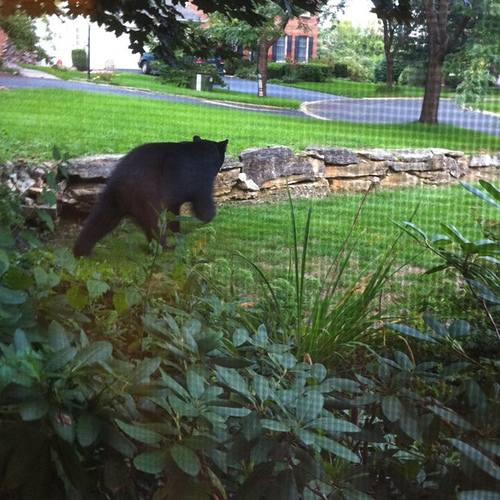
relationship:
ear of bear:
[190, 125, 206, 140] [90, 112, 255, 279]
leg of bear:
[191, 190, 214, 223] [73, 134, 229, 256]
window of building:
[292, 32, 309, 66] [166, 5, 321, 71]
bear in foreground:
[73, 134, 229, 256] [5, 126, 485, 490]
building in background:
[167, 0, 319, 63] [5, 5, 483, 158]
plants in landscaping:
[163, 219, 405, 418] [12, 170, 482, 496]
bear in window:
[73, 134, 229, 256] [3, 5, 497, 377]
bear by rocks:
[73, 134, 229, 256] [241, 140, 497, 189]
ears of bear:
[189, 130, 234, 149] [73, 134, 229, 256]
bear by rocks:
[73, 134, 229, 256] [0, 143, 500, 229]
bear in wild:
[56, 99, 263, 269] [38, 60, 468, 418]